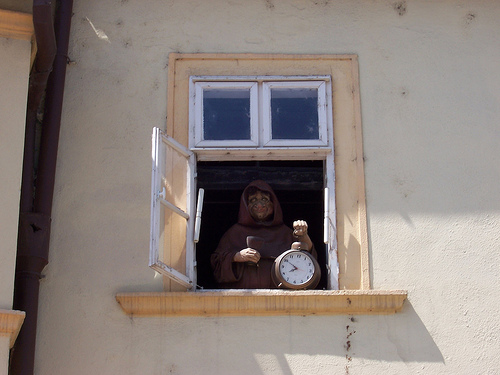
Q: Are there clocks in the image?
A: Yes, there is a clock.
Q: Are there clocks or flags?
A: Yes, there is a clock.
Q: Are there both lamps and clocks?
A: No, there is a clock but no lamps.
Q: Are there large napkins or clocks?
A: Yes, there is a large clock.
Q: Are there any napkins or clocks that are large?
A: Yes, the clock is large.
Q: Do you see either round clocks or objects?
A: Yes, there is a round clock.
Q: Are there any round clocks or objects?
A: Yes, there is a round clock.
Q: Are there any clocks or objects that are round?
A: Yes, the clock is round.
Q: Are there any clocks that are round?
A: Yes, there is a round clock.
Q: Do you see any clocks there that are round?
A: Yes, there is a clock that is round.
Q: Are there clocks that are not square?
A: Yes, there is a round clock.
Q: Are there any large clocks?
A: Yes, there is a large clock.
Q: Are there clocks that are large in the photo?
A: Yes, there is a large clock.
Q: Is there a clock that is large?
A: Yes, there is a clock that is large.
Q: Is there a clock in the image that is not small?
A: Yes, there is a large clock.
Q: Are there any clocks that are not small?
A: Yes, there is a large clock.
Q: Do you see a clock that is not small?
A: Yes, there is a large clock.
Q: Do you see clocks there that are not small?
A: Yes, there is a large clock.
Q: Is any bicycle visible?
A: No, there are no bicycles.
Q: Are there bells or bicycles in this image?
A: No, there are no bicycles or bells.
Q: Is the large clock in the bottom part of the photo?
A: Yes, the clock is in the bottom of the image.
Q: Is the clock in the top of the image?
A: No, the clock is in the bottom of the image.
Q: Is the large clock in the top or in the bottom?
A: The clock is in the bottom of the image.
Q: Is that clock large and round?
A: Yes, the clock is large and round.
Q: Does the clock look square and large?
A: No, the clock is large but round.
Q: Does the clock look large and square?
A: No, the clock is large but round.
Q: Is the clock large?
A: Yes, the clock is large.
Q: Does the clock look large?
A: Yes, the clock is large.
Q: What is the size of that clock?
A: The clock is large.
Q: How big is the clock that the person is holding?
A: The clock is large.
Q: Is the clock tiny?
A: No, the clock is large.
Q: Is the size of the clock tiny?
A: No, the clock is large.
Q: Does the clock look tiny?
A: No, the clock is large.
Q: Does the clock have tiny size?
A: No, the clock is large.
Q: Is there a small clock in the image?
A: No, there is a clock but it is large.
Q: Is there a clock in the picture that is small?
A: No, there is a clock but it is large.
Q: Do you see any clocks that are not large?
A: No, there is a clock but it is large.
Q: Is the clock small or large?
A: The clock is large.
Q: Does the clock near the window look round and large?
A: Yes, the clock is round and large.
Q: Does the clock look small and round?
A: No, the clock is round but large.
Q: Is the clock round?
A: Yes, the clock is round.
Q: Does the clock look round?
A: Yes, the clock is round.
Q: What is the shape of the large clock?
A: The clock is round.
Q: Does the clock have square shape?
A: No, the clock is round.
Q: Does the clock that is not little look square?
A: No, the clock is round.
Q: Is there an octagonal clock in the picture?
A: No, there is a clock but it is round.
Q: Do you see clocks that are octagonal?
A: No, there is a clock but it is round.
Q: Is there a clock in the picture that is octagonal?
A: No, there is a clock but it is round.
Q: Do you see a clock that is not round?
A: No, there is a clock but it is round.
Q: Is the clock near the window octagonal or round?
A: The clock is round.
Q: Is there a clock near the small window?
A: Yes, there is a clock near the window.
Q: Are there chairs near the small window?
A: No, there is a clock near the window.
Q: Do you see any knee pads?
A: No, there are no knee pads.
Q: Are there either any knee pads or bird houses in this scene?
A: No, there are no knee pads or bird houses.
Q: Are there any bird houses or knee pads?
A: No, there are no knee pads or bird houses.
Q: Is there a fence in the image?
A: No, there are no fences.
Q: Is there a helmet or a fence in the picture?
A: No, there are no fences or helmets.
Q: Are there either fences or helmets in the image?
A: No, there are no fences or helmets.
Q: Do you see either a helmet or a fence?
A: No, there are no fences or helmets.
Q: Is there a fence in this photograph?
A: No, there are no fences.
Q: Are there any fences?
A: No, there are no fences.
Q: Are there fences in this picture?
A: No, there are no fences.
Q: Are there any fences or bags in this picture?
A: No, there are no fences or bags.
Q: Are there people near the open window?
A: Yes, there is a person near the window.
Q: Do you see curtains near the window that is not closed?
A: No, there is a person near the window.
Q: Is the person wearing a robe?
A: Yes, the person is wearing a robe.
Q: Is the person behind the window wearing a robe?
A: Yes, the person is wearing a robe.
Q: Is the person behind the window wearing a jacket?
A: No, the person is wearing a robe.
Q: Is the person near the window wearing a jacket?
A: No, the person is wearing a robe.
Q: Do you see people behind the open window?
A: Yes, there is a person behind the window.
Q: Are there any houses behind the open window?
A: No, there is a person behind the window.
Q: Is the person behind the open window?
A: Yes, the person is behind the window.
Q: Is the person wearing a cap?
A: Yes, the person is wearing a cap.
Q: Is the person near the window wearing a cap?
A: Yes, the person is wearing a cap.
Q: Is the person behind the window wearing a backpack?
A: No, the person is wearing a cap.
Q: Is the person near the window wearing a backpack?
A: No, the person is wearing a cap.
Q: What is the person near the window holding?
A: The person is holding the clock.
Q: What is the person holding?
A: The person is holding the clock.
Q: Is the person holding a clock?
A: Yes, the person is holding a clock.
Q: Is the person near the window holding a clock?
A: Yes, the person is holding a clock.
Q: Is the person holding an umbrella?
A: No, the person is holding a clock.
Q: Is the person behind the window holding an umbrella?
A: No, the person is holding a clock.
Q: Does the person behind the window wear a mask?
A: Yes, the person wears a mask.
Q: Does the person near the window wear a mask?
A: Yes, the person wears a mask.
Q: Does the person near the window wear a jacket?
A: No, the person wears a mask.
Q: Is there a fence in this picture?
A: No, there are no fences.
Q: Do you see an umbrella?
A: No, there are no umbrellas.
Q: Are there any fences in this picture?
A: No, there are no fences.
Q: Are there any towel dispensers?
A: No, there are no towel dispensers.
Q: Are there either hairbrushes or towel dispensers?
A: No, there are no towel dispensers or hairbrushes.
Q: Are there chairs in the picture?
A: No, there are no chairs.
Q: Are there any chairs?
A: No, there are no chairs.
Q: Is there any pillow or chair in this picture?
A: No, there are no chairs or pillows.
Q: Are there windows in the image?
A: Yes, there is a window.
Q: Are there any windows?
A: Yes, there is a window.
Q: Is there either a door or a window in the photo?
A: Yes, there is a window.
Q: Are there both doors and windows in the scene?
A: No, there is a window but no doors.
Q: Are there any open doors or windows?
A: Yes, there is an open window.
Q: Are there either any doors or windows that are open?
A: Yes, the window is open.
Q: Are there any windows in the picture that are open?
A: Yes, there is an open window.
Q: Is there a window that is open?
A: Yes, there is a window that is open.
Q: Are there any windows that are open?
A: Yes, there is a window that is open.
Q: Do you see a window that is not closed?
A: Yes, there is a open window.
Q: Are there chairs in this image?
A: No, there are no chairs.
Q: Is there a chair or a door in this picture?
A: No, there are no chairs or doors.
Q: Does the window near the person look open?
A: Yes, the window is open.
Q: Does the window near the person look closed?
A: No, the window is open.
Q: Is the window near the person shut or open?
A: The window is open.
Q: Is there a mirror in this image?
A: No, there are no mirrors.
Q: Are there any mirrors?
A: No, there are no mirrors.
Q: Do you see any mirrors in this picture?
A: No, there are no mirrors.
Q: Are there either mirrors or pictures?
A: No, there are no mirrors or pictures.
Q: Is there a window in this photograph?
A: Yes, there is a window.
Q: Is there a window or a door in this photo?
A: Yes, there is a window.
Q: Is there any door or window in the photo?
A: Yes, there is a window.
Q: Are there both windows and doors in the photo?
A: No, there is a window but no doors.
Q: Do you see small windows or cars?
A: Yes, there is a small window.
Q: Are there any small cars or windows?
A: Yes, there is a small window.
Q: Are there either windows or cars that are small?
A: Yes, the window is small.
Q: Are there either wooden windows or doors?
A: Yes, there is a wood window.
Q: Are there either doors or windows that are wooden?
A: Yes, the window is wooden.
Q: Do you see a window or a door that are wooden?
A: Yes, the window is wooden.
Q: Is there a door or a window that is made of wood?
A: Yes, the window is made of wood.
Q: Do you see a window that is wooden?
A: Yes, there is a wood window.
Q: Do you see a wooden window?
A: Yes, there is a wood window.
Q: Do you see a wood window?
A: Yes, there is a window that is made of wood.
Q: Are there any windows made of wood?
A: Yes, there is a window that is made of wood.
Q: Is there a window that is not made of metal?
A: Yes, there is a window that is made of wood.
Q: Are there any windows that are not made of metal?
A: Yes, there is a window that is made of wood.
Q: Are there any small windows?
A: Yes, there is a small window.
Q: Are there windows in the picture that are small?
A: Yes, there is a window that is small.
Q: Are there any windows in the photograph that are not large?
A: Yes, there is a small window.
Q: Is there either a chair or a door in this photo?
A: No, there are no chairs or doors.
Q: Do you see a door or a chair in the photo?
A: No, there are no chairs or doors.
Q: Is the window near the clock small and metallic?
A: No, the window is small but wooden.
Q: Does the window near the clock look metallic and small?
A: No, the window is small but wooden.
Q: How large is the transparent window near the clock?
A: The window is small.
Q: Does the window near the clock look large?
A: No, the window is small.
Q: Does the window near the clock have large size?
A: No, the window is small.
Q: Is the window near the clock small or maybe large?
A: The window is small.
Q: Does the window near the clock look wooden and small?
A: Yes, the window is wooden and small.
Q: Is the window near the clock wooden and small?
A: Yes, the window is wooden and small.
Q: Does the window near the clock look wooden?
A: Yes, the window is wooden.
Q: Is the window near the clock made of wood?
A: Yes, the window is made of wood.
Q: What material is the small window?
A: The window is made of wood.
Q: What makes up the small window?
A: The window is made of wood.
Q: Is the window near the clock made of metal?
A: No, the window is made of wood.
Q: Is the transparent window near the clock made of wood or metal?
A: The window is made of wood.